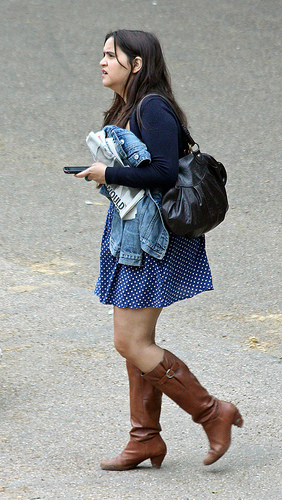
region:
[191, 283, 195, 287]
white dot on dress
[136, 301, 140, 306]
white dot on dress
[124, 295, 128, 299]
white dot on dress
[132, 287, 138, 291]
white dot on dress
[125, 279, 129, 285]
white dot on dress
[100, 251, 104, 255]
white dot on dress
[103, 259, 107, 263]
white dot on dress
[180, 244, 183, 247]
white dot on dress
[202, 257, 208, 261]
white dot on dress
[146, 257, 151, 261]
white dot on dress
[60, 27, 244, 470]
a young woman with dark hair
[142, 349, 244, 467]
a brown boot with a silver buckle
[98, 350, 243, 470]
two brown boots with heels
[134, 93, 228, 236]
a black leather hand bag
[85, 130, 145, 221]
a folded up newspaper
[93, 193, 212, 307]
a short blue skirt with white polka dots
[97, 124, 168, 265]
a blue denim jacket with silver buttons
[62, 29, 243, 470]
a young woman holding a cell phone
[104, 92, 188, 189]
a light weight navy blue sweater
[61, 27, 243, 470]
a young woman wearing brown leather boots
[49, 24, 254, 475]
she is walking in the street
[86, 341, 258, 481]
a pair of brown boots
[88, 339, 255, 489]
these are brown leather boots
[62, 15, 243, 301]
she is wearing a dress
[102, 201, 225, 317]
her dress has white polka dots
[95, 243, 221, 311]
there are white dots on the dress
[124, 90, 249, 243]
a black leather purse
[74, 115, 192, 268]
she is holding a denim jacket and a news paper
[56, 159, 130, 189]
she is holding a cell phone in her hand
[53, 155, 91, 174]
the phone is black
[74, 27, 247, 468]
this is a person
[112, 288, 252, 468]
this is a leg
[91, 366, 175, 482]
this is a leg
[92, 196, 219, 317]
a blue dotted dress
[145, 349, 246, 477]
this is a boot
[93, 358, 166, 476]
this is a boot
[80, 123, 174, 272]
this is a jeans jacket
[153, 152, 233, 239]
this is a black bag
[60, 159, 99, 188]
this is a phone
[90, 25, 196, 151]
the lady has long hair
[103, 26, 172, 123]
a woman with long hair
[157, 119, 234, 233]
a black leather purse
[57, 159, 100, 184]
a woman holding a cell phone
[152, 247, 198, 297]
a woman wearing a blue dress with white dots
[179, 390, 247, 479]
a woman with one foot raised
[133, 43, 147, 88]
a woman with her hair behind her ear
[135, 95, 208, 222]
a woman carrying a purse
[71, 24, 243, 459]
A person is standing up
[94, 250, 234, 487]
A person walking on a sidewalk.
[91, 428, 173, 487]
bottom of the shoe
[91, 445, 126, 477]
tip of the foot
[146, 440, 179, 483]
heel of the shoe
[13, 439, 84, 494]
ground next to the girl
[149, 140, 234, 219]
bag next to the girl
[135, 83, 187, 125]
strap around the shoulder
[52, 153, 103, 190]
phone in girl's hand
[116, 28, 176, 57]
hair on the girl's head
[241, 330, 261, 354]
Dirt is on the gravel.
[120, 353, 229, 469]
The lady has brown boots.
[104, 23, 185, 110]
The lady has brown hair.